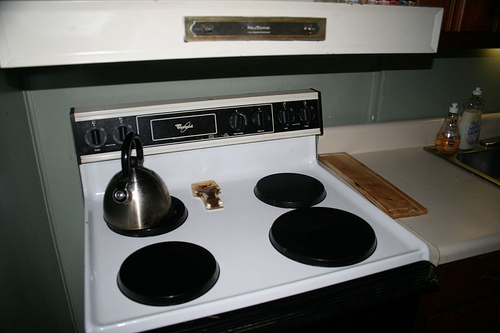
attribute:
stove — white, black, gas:
[75, 98, 326, 292]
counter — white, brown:
[359, 154, 464, 222]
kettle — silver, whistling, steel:
[104, 149, 163, 234]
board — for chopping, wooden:
[329, 149, 422, 224]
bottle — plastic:
[441, 101, 460, 156]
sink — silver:
[466, 150, 500, 170]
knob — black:
[230, 111, 252, 137]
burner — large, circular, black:
[123, 241, 207, 296]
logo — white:
[166, 122, 196, 135]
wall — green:
[132, 82, 231, 101]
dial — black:
[88, 127, 107, 151]